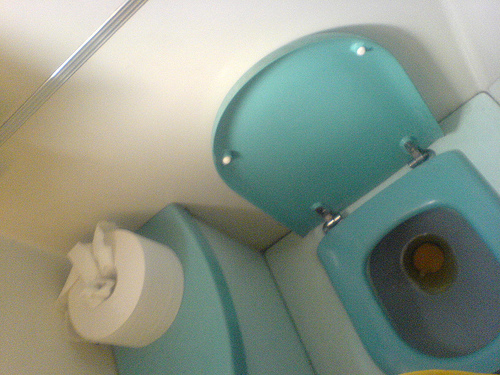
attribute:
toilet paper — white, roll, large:
[61, 224, 181, 348]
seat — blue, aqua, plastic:
[315, 153, 499, 372]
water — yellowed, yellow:
[404, 235, 458, 296]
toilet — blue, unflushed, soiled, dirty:
[210, 33, 497, 358]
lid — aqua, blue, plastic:
[210, 28, 445, 240]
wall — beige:
[1, 246, 112, 372]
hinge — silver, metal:
[403, 135, 433, 170]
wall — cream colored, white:
[5, 3, 498, 243]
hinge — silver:
[313, 202, 343, 229]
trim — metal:
[1, 1, 141, 146]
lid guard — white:
[357, 44, 369, 61]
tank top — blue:
[105, 201, 248, 374]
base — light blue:
[214, 90, 500, 374]